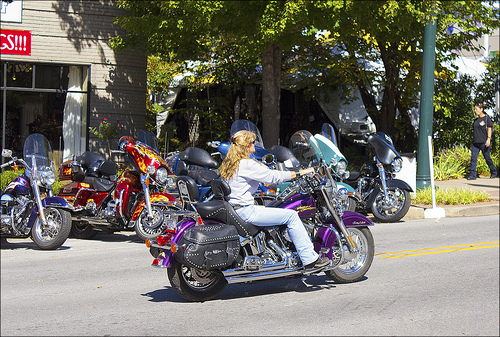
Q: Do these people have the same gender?
A: Yes, all the people are female.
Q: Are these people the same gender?
A: Yes, all the people are female.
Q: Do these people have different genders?
A: No, all the people are female.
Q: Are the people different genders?
A: No, all the people are female.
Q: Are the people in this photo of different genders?
A: No, all the people are female.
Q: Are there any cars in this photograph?
A: No, there are no cars.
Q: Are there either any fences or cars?
A: No, there are no cars or fences.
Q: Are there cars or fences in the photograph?
A: No, there are no cars or fences.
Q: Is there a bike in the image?
A: Yes, there is a bike.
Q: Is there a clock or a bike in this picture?
A: Yes, there is a bike.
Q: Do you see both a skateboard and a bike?
A: No, there is a bike but no skateboards.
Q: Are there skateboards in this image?
A: No, there are no skateboards.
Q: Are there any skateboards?
A: No, there are no skateboards.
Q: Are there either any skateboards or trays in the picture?
A: No, there are no skateboards or trays.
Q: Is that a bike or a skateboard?
A: That is a bike.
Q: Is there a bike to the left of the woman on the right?
A: Yes, there is a bike to the left of the woman.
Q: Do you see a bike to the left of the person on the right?
A: Yes, there is a bike to the left of the woman.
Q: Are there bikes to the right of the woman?
A: No, the bike is to the left of the woman.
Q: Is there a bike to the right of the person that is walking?
A: No, the bike is to the left of the woman.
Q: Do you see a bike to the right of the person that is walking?
A: No, the bike is to the left of the woman.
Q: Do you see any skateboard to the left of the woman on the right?
A: No, there is a bike to the left of the woman.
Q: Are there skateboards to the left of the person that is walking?
A: No, there is a bike to the left of the woman.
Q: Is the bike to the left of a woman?
A: Yes, the bike is to the left of a woman.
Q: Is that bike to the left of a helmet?
A: No, the bike is to the left of a woman.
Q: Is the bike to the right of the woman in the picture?
A: No, the bike is to the left of the woman.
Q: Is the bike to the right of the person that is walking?
A: No, the bike is to the left of the woman.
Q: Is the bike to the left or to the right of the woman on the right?
A: The bike is to the left of the woman.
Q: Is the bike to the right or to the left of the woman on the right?
A: The bike is to the left of the woman.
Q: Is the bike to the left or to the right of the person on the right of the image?
A: The bike is to the left of the woman.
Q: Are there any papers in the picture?
A: No, there are no papers.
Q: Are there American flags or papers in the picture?
A: No, there are no papers or American flags.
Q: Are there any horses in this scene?
A: No, there are no horses.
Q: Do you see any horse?
A: No, there are no horses.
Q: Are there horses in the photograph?
A: No, there are no horses.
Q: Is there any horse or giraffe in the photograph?
A: No, there are no horses or giraffes.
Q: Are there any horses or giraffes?
A: No, there are no horses or giraffes.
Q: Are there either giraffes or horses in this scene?
A: No, there are no horses or giraffes.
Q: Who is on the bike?
A: The lady is on the bike.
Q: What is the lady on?
A: The lady is on the bike.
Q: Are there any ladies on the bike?
A: Yes, there is a lady on the bike.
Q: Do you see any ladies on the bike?
A: Yes, there is a lady on the bike.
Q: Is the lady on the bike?
A: Yes, the lady is on the bike.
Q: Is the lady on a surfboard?
A: No, the lady is on the bike.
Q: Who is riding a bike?
A: The lady is riding a bike.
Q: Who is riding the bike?
A: The lady is riding a bike.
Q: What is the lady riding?
A: The lady is riding a bike.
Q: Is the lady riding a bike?
A: Yes, the lady is riding a bike.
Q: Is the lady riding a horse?
A: No, the lady is riding a bike.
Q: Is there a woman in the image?
A: Yes, there is a woman.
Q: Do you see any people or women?
A: Yes, there is a woman.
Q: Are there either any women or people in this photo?
A: Yes, there is a woman.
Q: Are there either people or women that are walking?
A: Yes, the woman is walking.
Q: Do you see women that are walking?
A: Yes, there is a woman that is walking.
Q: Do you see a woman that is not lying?
A: Yes, there is a woman that is walking .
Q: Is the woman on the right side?
A: Yes, the woman is on the right of the image.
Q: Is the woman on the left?
A: No, the woman is on the right of the image.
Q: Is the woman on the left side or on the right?
A: The woman is on the right of the image.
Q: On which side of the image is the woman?
A: The woman is on the right of the image.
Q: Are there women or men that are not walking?
A: No, there is a woman but she is walking.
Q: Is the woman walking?
A: Yes, the woman is walking.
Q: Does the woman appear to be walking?
A: Yes, the woman is walking.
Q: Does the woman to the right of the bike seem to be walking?
A: Yes, the woman is walking.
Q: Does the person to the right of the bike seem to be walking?
A: Yes, the woman is walking.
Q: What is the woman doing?
A: The woman is walking.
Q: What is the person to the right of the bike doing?
A: The woman is walking.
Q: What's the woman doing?
A: The woman is walking.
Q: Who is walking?
A: The woman is walking.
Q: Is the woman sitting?
A: No, the woman is walking.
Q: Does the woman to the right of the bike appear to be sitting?
A: No, the woman is walking.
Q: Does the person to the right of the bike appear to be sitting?
A: No, the woman is walking.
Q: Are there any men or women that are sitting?
A: No, there is a woman but she is walking.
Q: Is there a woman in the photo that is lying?
A: No, there is a woman but she is walking.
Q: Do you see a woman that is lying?
A: No, there is a woman but she is walking.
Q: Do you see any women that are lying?
A: No, there is a woman but she is walking.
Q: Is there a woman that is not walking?
A: No, there is a woman but she is walking.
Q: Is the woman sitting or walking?
A: The woman is walking.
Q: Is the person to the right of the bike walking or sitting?
A: The woman is walking.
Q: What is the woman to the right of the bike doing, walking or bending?
A: The woman is walking.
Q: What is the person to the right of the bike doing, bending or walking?
A: The woman is walking.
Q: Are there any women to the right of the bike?
A: Yes, there is a woman to the right of the bike.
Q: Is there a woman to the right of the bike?
A: Yes, there is a woman to the right of the bike.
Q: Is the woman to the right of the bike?
A: Yes, the woman is to the right of the bike.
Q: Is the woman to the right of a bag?
A: No, the woman is to the right of the bike.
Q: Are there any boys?
A: No, there are no boys.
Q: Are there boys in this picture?
A: No, there are no boys.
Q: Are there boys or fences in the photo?
A: No, there are no boys or fences.